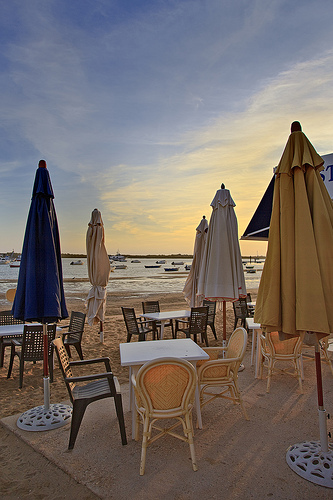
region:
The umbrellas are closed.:
[10, 120, 332, 337]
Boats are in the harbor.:
[2, 255, 265, 281]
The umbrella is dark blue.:
[11, 158, 69, 324]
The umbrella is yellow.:
[253, 119, 331, 341]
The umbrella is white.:
[197, 183, 248, 303]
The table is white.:
[119, 337, 210, 366]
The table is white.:
[140, 307, 191, 337]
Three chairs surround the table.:
[53, 325, 251, 474]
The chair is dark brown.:
[53, 336, 128, 450]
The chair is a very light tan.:
[129, 356, 200, 475]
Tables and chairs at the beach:
[0, 296, 305, 490]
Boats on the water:
[3, 250, 267, 282]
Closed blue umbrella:
[9, 153, 68, 431]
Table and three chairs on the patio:
[52, 325, 247, 473]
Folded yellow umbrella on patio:
[252, 120, 330, 488]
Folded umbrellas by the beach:
[80, 183, 247, 347]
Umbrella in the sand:
[84, 206, 112, 354]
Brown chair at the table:
[52, 334, 128, 453]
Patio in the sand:
[0, 349, 331, 496]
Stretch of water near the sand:
[0, 274, 272, 292]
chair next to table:
[128, 351, 209, 488]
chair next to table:
[51, 327, 127, 452]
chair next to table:
[207, 323, 242, 417]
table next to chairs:
[111, 335, 212, 354]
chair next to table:
[116, 303, 137, 329]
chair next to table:
[186, 304, 213, 334]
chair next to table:
[67, 304, 84, 348]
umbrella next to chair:
[13, 145, 68, 326]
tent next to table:
[202, 181, 242, 288]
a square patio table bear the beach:
[116, 337, 209, 437]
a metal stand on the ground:
[16, 376, 74, 431]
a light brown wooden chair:
[130, 357, 200, 473]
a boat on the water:
[109, 250, 123, 261]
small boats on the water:
[73, 259, 262, 278]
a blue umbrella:
[12, 159, 69, 325]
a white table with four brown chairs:
[119, 300, 219, 348]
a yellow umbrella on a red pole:
[255, 120, 332, 407]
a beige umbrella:
[198, 190, 247, 302]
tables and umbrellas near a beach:
[0, 120, 329, 497]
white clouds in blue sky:
[9, 27, 54, 71]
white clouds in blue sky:
[21, 96, 78, 126]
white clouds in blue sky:
[75, 27, 139, 103]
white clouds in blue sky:
[69, 121, 130, 179]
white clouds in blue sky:
[150, 18, 218, 84]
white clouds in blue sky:
[190, 34, 247, 152]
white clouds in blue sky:
[246, 47, 297, 105]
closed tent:
[16, 174, 74, 328]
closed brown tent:
[81, 208, 112, 296]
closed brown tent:
[204, 182, 247, 298]